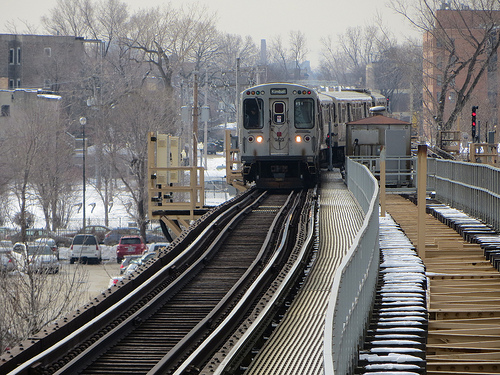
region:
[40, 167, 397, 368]
tracks for train or subway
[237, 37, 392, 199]
train travelling along tracks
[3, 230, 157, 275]
a group of cars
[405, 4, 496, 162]
tall brown building behind tree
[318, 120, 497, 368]
platform area for train passengers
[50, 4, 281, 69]
trees against grey skies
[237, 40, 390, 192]
grey train on tracks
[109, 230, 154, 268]
a red motor vehicle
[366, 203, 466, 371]
white snow covering wood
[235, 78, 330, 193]
person in left train window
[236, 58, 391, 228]
train travelling on elevated train track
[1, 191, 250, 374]
long elevated metal train track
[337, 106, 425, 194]
train wait station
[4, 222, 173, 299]
cars parked in parking lot benath train platfom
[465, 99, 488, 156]
traffic light wiith two red lights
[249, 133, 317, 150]
two headlights on front of train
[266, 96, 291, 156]
door on front of train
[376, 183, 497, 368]
wooden spokes beside train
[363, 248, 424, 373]
snow covered metal spokes next to train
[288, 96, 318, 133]
black framed window on train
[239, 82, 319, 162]
the back of a train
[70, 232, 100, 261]
back of a white suv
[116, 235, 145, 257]
back of a red suv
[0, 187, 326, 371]
train tracks and cars in a lot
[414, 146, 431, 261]
a wooden post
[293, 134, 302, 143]
light on a train car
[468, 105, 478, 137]
a streetlight with red lights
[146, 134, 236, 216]
a metal platform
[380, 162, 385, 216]
a wooden post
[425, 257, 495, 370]
a wooden walkway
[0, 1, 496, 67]
a dismal grey sky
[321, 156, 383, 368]
a railing next to the tracks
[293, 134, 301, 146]
a headlight on a train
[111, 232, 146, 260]
a red vehicle in a parking lot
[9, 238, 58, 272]
a white minivan in a parking lot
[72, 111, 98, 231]
a light pole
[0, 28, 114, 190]
a large brick building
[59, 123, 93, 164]
stairs on a building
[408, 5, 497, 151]
a bare leafless tree next to the tracks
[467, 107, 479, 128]
a red light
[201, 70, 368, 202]
a train on the tracks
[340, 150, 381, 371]
a fence beside the tracks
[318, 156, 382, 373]
the fence is metal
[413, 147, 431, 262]
a post near the tracks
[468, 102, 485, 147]
a red traffic light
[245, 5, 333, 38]
the sky is cloudy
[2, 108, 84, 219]
trees without leaves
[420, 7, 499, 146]
the tallest building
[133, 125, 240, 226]
a platform beside the train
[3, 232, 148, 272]
the cars are parked